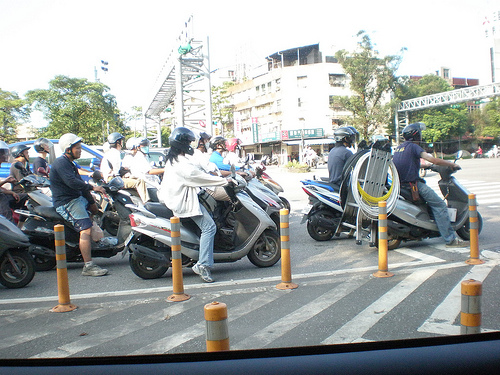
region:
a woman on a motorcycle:
[125, 127, 287, 276]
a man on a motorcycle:
[27, 132, 139, 277]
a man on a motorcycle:
[360, 124, 482, 244]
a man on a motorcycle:
[302, 124, 372, 241]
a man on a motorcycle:
[3, 144, 48, 198]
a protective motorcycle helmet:
[56, 134, 82, 147]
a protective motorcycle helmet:
[165, 124, 196, 147]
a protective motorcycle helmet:
[106, 131, 123, 143]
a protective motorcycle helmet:
[209, 134, 224, 148]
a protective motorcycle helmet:
[223, 134, 240, 151]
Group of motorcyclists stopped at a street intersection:
[15, 121, 479, 268]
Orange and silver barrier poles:
[44, 198, 489, 277]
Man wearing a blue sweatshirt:
[50, 127, 125, 279]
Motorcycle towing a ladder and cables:
[345, 149, 482, 245]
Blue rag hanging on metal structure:
[173, 31, 209, 71]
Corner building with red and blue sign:
[275, 58, 332, 168]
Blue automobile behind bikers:
[8, 127, 114, 194]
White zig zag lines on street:
[82, 253, 497, 350]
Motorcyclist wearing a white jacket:
[157, 137, 237, 287]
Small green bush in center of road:
[283, 155, 313, 176]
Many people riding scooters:
[24, 126, 452, 272]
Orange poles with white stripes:
[38, 203, 486, 272]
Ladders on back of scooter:
[329, 114, 474, 264]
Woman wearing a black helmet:
[149, 118, 221, 219]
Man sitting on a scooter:
[40, 128, 113, 240]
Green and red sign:
[273, 126, 339, 142]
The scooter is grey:
[99, 183, 284, 278]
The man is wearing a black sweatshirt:
[42, 121, 109, 228]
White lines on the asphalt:
[29, 277, 482, 350]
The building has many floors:
[206, 44, 406, 169]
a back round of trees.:
[0, 55, 120, 135]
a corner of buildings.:
[210, 35, 355, 135]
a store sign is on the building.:
[270, 120, 325, 135]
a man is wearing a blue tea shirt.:
[390, 145, 430, 180]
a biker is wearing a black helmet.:
[400, 125, 425, 140]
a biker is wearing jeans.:
[415, 180, 450, 245]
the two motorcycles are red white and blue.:
[295, 160, 400, 240]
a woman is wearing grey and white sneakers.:
[185, 260, 216, 277]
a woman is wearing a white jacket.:
[157, 155, 217, 217]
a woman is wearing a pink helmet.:
[223, 130, 244, 161]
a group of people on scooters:
[5, 111, 480, 273]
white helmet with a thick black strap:
[53, 128, 88, 165]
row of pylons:
[43, 192, 495, 319]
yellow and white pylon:
[158, 217, 205, 304]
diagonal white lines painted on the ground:
[16, 262, 498, 374]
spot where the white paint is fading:
[10, 300, 148, 346]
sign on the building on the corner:
[277, 123, 328, 146]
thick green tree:
[402, 65, 469, 168]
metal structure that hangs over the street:
[383, 74, 499, 158]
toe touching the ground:
[188, 263, 225, 285]